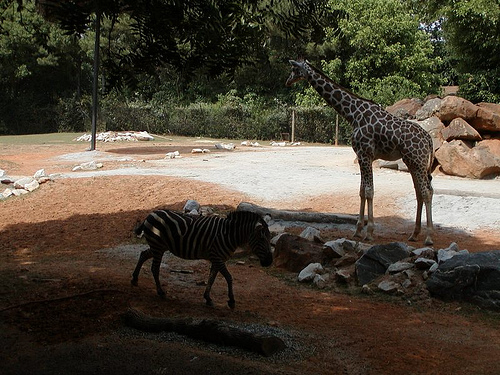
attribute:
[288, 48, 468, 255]
giraffe — brown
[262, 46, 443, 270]
giraffe — brown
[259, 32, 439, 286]
giraffe — brown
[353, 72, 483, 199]
rocks — pile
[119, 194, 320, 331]
zebra — walking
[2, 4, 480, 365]
enclosure — zoo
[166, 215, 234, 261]
torso — zebra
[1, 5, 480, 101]
leaves — green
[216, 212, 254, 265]
neck — zebra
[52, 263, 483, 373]
surface — ground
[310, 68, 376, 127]
neck — long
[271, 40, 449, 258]
giraffe — brown, standing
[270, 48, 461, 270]
giraffe — brown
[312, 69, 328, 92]
spots — brown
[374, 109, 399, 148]
brown spots — on a giraffe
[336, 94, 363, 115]
brown spots — on a giraffe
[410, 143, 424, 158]
brown spots — on a giraffe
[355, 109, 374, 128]
brown spots — on a giraffe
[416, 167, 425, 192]
brown spots — on a giraffe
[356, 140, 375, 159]
brown spots — on a giraffe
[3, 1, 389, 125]
green leaves — on trees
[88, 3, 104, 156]
vertical pole — in dirt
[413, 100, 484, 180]
rocks — in enclosure